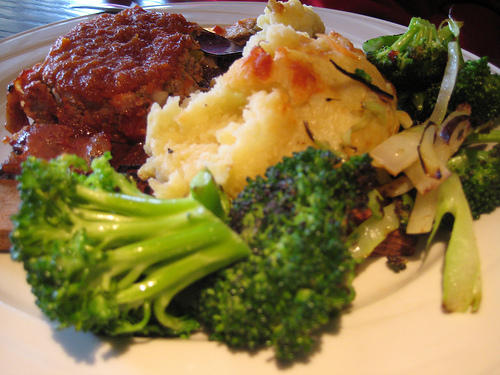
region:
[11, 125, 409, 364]
Pieces of cooked broccoli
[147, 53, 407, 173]
Mash potatoes in middle of dish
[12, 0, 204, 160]
Stew on a dish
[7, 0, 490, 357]
Meal on a white dish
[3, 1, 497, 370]
Meal with meat, mash potatoes and broccoli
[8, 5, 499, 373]
Dish is white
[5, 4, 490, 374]
White round dish has food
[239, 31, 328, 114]
Mash potato has red spots on top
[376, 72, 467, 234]
Slices of green vegetables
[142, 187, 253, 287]
Stem of broccoli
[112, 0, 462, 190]
mash potato on plate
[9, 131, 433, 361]
crowns of broccoli on plate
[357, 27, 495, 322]
fried onions on plate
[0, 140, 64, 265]
meat on plate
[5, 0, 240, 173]
meat loaf on plate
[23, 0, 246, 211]
tomato sauce on meatloaf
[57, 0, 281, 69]
black fork on plate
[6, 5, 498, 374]
white plate with food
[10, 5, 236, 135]
mince meat on plate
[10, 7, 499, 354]
broccoli crowns round plate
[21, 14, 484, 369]
There is broccoli on the plate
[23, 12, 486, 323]
There is mash potatoes on the plate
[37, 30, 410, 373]
The mash potatoes are next to the broccoli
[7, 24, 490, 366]
The plate is white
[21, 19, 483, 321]
The plate is on a brown table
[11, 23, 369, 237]
There is red sauce on the plate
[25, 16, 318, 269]
There is food with red sauce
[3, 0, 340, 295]
Light is shining on the table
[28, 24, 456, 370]
There is food on a white plate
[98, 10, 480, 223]
Mash potatoes are in the middle of the plate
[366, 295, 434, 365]
the plate is white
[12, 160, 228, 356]
the plants are green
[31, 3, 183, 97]
the meat is red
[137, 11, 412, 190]
the potatoes are white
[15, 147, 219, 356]
the vegetable is green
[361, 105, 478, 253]
the onions are white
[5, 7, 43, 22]
the wood is black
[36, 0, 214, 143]
the meat is mushy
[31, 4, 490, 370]
the food is cooked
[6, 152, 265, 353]
the food is shiny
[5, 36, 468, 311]
this is a food on the plate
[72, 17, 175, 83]
the beef is fresh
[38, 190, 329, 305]
the vegetables are green in color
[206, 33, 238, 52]
this is a fork on the food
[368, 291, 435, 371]
this is a plate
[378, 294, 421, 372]
the plate is white in color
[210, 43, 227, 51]
the fork is metallic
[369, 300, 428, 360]
the plate is flat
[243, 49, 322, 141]
the food is yellow in color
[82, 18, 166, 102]
the beef is brown in color